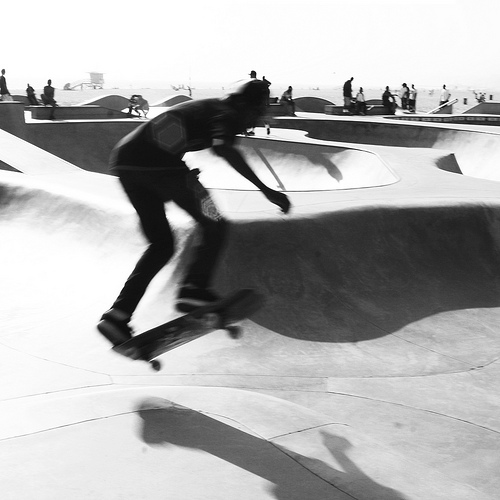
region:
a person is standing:
[123, 91, 140, 122]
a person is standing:
[331, 70, 356, 107]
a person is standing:
[354, 81, 366, 106]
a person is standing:
[396, 82, 410, 109]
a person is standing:
[406, 81, 421, 111]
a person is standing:
[436, 82, 450, 108]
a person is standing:
[40, 76, 61, 117]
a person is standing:
[0, 74, 14, 101]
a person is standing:
[25, 82, 35, 104]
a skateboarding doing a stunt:
[57, 50, 346, 395]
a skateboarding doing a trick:
[71, 57, 368, 378]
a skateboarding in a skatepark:
[35, 43, 347, 407]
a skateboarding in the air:
[69, 57, 333, 382]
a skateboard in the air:
[59, 282, 343, 389]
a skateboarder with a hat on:
[194, 45, 314, 155]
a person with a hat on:
[190, 64, 307, 189]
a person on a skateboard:
[57, 52, 329, 399]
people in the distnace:
[323, 74, 479, 127]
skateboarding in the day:
[39, 75, 336, 420]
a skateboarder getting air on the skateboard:
[88, 77, 297, 381]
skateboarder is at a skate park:
[1, 80, 498, 465]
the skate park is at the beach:
[0, 50, 497, 229]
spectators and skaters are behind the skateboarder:
[2, 65, 497, 187]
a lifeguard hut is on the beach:
[61, 67, 108, 94]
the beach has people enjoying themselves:
[10, 70, 497, 115]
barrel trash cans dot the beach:
[460, 90, 498, 106]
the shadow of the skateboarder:
[92, 79, 421, 497]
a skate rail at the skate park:
[418, 95, 465, 116]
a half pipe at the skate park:
[18, 115, 162, 201]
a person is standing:
[23, 77, 41, 113]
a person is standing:
[243, 61, 269, 137]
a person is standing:
[277, 80, 295, 114]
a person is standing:
[337, 74, 354, 119]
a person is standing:
[351, 83, 371, 124]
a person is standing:
[383, 84, 399, 124]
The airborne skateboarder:
[88, 81, 295, 373]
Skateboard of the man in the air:
[113, 283, 268, 375]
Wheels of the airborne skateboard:
[122, 313, 249, 370]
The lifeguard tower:
[68, 70, 106, 97]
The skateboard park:
[1, 88, 498, 498]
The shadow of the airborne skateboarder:
[122, 390, 412, 498]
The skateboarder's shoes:
[94, 289, 226, 344]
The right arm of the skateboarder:
[212, 134, 299, 214]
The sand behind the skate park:
[14, 83, 493, 114]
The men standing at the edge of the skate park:
[0, 66, 460, 124]